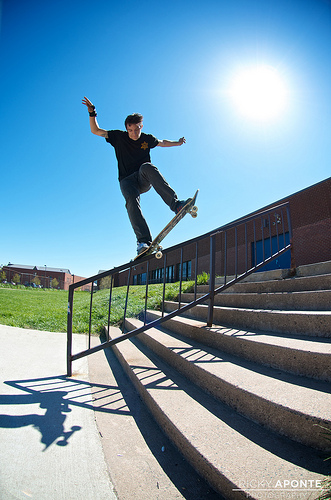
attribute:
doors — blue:
[253, 240, 286, 270]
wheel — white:
[149, 252, 163, 257]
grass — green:
[31, 290, 57, 304]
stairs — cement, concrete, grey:
[233, 310, 309, 447]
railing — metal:
[68, 275, 242, 357]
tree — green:
[27, 268, 43, 290]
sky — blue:
[64, 15, 156, 80]